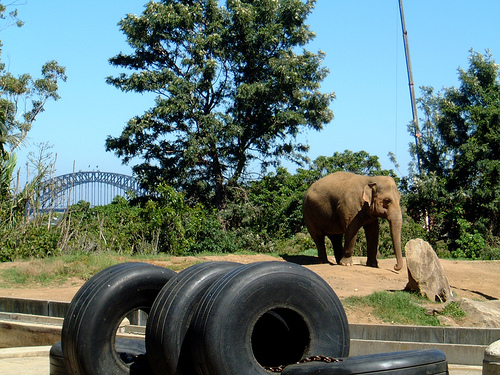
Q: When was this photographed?
A: Day time.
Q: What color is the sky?
A: Blue.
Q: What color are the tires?
A: Black.